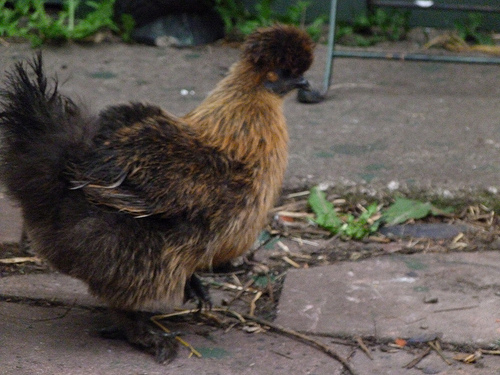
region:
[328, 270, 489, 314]
The ground is made of concrete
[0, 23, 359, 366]
The chicken is on the ground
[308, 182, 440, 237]
The leaf is growing out of the concrete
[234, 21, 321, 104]
The head of the chicken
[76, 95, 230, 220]
The wing of the chicken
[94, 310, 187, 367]
The feet of the chicken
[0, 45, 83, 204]
The tail of the chicken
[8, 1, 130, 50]
The leaves are very green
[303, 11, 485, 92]
The pole is made of metal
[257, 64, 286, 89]
The eye of the chicken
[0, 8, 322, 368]
fancy chicken is silkie, in brown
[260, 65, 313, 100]
the tiny black face of a little silkie chicken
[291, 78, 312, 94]
a dark blue-grey bill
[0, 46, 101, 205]
tail feathers a bit ruffled from wandering the streets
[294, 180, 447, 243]
broken leaves on the road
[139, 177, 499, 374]
broken straw, broken branches, & dirt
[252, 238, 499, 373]
a piece of broken road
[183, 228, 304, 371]
green paint splots amid the road mess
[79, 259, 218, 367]
2 5-toed silkie feet, w/ feathers all over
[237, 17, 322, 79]
the chicken version of a cartoon moptop hairdo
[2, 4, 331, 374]
a chicken on the ground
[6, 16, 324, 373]
the bird is brown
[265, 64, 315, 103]
the black face of the bird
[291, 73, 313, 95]
the black beak of the bird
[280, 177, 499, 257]
the twigs and leaves in the cracks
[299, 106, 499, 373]
cracks in the pavement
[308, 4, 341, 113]
the green leg of a chair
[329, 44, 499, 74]
the green bar on the chair legs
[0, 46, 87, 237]
the tail feathers of the bird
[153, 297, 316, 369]
twigs under the small brown bird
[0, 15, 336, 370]
This is a hen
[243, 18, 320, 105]
Head of a hen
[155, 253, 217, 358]
Leg of a hen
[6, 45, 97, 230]
Tail of a hen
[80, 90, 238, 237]
Tail of a hen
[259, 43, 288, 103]
Eye of a hen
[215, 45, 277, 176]
Neck of a hen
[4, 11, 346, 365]
This is a brown hen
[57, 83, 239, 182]
Back of a hen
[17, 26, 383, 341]
Head of a hen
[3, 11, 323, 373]
THE CHICKEN IS A BANTY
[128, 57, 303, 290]
THE CHICKEN HAS BROWN FEATHERS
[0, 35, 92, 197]
THE CHICKEN HAS BLACK TAIL FEATHERS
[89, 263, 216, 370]
THE CHICKEN HAS BLACK FEET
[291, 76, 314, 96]
THE CHICKEN HAS A BLACK BEAK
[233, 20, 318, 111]
THE CHICKEN HAS A PUFFY TOP KNOT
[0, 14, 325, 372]
THE CHICKEN IS A HEN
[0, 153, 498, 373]
THE SIDEWALK IS CRACKED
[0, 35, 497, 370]
THE SIDEWALK IS BROWN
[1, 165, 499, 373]
THE WEEDS ARE GROWING IN THE CRACKS